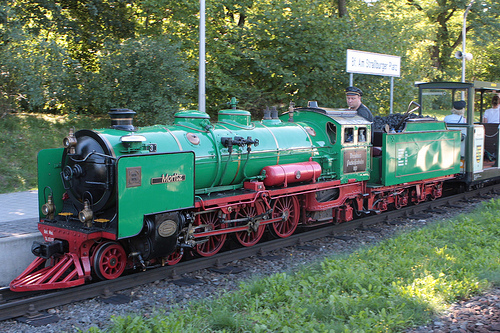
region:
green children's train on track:
[30, 98, 493, 234]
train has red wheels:
[205, 190, 320, 260]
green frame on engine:
[100, 102, 492, 205]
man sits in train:
[345, 92, 388, 162]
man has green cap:
[345, 81, 358, 97]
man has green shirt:
[350, 103, 381, 130]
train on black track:
[0, 277, 50, 318]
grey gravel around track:
[65, 270, 205, 320]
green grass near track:
[95, 181, 498, 316]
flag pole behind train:
[172, 3, 224, 125]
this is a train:
[6, 50, 441, 292]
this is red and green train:
[35, 15, 320, 265]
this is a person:
[317, 55, 388, 198]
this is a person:
[425, 60, 495, 155]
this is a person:
[475, 70, 495, 130]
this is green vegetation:
[10, 10, 162, 105]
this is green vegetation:
[207, 300, 383, 330]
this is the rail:
[11, 205, 418, 289]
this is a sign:
[339, 41, 416, 81]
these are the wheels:
[98, 188, 315, 278]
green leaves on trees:
[5, 1, 498, 113]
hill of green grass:
[2, 112, 104, 189]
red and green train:
[10, 77, 495, 297]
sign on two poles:
[345, 46, 400, 103]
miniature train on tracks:
[11, 80, 496, 300]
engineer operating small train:
[305, 83, 372, 179]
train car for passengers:
[418, 77, 498, 178]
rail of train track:
[0, 191, 480, 326]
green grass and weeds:
[119, 218, 496, 332]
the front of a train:
[33, 118, 142, 252]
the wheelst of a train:
[69, 188, 236, 294]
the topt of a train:
[84, 88, 310, 173]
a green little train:
[58, 85, 290, 288]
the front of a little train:
[10, 111, 176, 251]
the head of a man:
[339, 78, 366, 118]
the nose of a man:
[336, 79, 379, 115]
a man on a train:
[249, 75, 386, 190]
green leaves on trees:
[192, 0, 342, 100]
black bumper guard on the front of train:
[27, 237, 59, 260]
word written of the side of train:
[149, 170, 187, 187]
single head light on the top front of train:
[60, 126, 76, 153]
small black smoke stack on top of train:
[107, 105, 134, 128]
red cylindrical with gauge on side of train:
[262, 163, 323, 184]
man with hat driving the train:
[342, 83, 374, 146]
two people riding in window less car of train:
[444, 90, 499, 122]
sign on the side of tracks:
[342, 43, 406, 85]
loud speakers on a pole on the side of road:
[447, 44, 476, 66]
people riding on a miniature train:
[28, 75, 497, 187]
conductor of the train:
[340, 82, 380, 142]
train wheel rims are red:
[191, 202, 296, 239]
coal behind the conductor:
[370, 107, 421, 128]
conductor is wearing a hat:
[340, 82, 361, 109]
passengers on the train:
[440, 93, 498, 124]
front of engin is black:
[58, 128, 114, 213]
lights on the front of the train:
[39, 126, 91, 224]